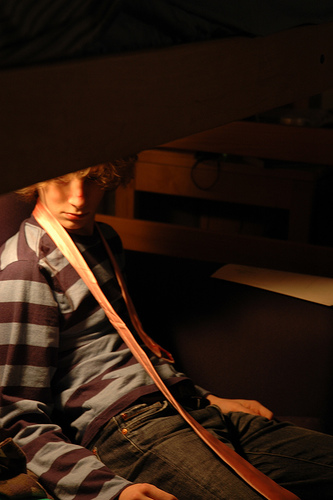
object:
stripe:
[26, 214, 44, 229]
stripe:
[17, 220, 37, 262]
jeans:
[85, 390, 333, 500]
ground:
[256, 87, 282, 109]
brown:
[0, 141, 333, 500]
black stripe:
[0, 263, 52, 286]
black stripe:
[0, 342, 53, 368]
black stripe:
[51, 262, 80, 294]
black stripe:
[0, 301, 59, 332]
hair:
[15, 160, 136, 203]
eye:
[82, 178, 103, 191]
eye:
[54, 179, 69, 189]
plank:
[0, 31, 333, 195]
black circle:
[188, 153, 221, 191]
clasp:
[121, 428, 127, 435]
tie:
[30, 199, 298, 499]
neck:
[32, 203, 108, 245]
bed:
[0, 0, 333, 309]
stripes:
[65, 370, 120, 418]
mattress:
[136, 116, 333, 216]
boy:
[0, 155, 333, 499]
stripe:
[38, 445, 92, 490]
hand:
[206, 397, 273, 424]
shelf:
[90, 142, 332, 311]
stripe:
[16, 431, 74, 463]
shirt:
[1, 203, 187, 499]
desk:
[87, 119, 332, 306]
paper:
[210, 261, 332, 309]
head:
[17, 160, 121, 232]